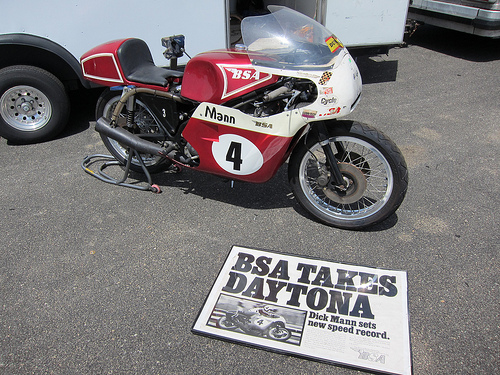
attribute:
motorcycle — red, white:
[69, 42, 369, 204]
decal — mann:
[190, 104, 241, 130]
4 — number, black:
[222, 139, 239, 178]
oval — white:
[209, 135, 260, 174]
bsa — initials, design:
[231, 68, 262, 80]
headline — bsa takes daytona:
[231, 249, 399, 319]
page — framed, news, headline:
[210, 247, 413, 369]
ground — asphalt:
[26, 119, 471, 358]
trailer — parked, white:
[0, 7, 409, 85]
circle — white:
[214, 134, 253, 176]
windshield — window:
[237, 17, 336, 69]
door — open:
[229, 5, 312, 49]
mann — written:
[200, 106, 235, 123]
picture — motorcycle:
[220, 295, 296, 342]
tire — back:
[94, 83, 179, 164]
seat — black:
[111, 42, 181, 80]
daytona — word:
[228, 271, 382, 326]